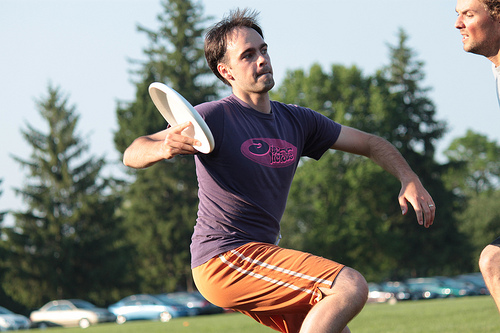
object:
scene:
[1, 0, 500, 333]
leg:
[205, 240, 381, 333]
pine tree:
[112, 0, 218, 292]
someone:
[454, 0, 498, 320]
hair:
[196, 5, 264, 87]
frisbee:
[145, 80, 222, 158]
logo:
[224, 122, 312, 187]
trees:
[371, 22, 456, 279]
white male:
[123, 7, 437, 331]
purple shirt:
[148, 96, 341, 270]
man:
[116, 7, 441, 331]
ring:
[427, 201, 437, 208]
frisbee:
[131, 77, 218, 164]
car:
[0, 267, 496, 333]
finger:
[425, 197, 437, 223]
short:
[187, 239, 347, 331]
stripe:
[205, 245, 331, 296]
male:
[127, 8, 440, 333]